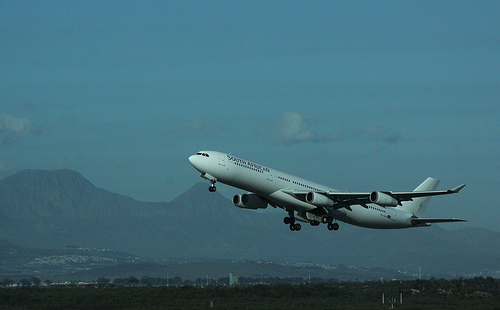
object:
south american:
[227, 155, 270, 172]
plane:
[187, 149, 468, 231]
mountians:
[169, 181, 241, 211]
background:
[0, 0, 495, 283]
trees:
[128, 277, 139, 285]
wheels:
[332, 223, 339, 231]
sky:
[0, 0, 499, 168]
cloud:
[278, 109, 321, 145]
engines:
[305, 192, 333, 207]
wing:
[292, 183, 468, 200]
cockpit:
[188, 150, 220, 173]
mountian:
[1, 168, 139, 204]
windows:
[196, 153, 201, 155]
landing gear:
[285, 206, 294, 217]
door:
[219, 155, 225, 165]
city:
[0, 246, 500, 286]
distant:
[0, 246, 499, 310]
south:
[227, 155, 247, 165]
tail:
[396, 176, 440, 216]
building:
[229, 273, 238, 285]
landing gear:
[200, 172, 217, 186]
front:
[188, 151, 265, 197]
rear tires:
[295, 223, 301, 231]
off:
[187, 149, 466, 231]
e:
[370, 190, 398, 205]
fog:
[0, 0, 499, 274]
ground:
[0, 302, 499, 310]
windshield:
[205, 154, 209, 157]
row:
[235, 162, 264, 173]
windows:
[289, 180, 291, 182]